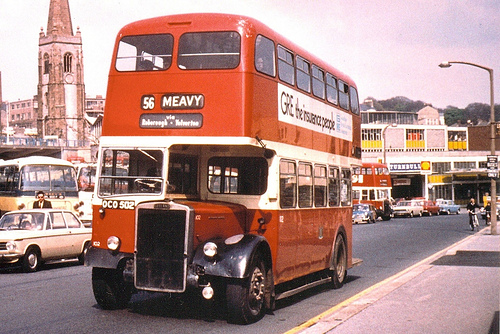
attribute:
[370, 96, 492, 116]
trees — distant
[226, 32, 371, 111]
windows — some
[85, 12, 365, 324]
bus — double decker, red , one, doubledecker, red and white, white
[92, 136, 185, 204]
window — glass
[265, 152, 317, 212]
window — glass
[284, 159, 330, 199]
window — glass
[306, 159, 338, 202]
window — glass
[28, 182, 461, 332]
street — asphault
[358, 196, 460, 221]
cars — lining, old-fashioned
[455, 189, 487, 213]
person — riding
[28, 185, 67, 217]
man — walking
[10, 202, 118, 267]
car — parked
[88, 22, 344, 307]
bus — red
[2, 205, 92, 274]
car — white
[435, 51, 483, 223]
light — STREET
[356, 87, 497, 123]
trees — green, leafy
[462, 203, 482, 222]
sweater — black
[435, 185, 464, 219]
car — blue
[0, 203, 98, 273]
car — gray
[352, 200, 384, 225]
car — green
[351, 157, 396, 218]
truck — red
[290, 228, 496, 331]
sidewalk — red, bricked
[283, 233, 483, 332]
curb — yellow